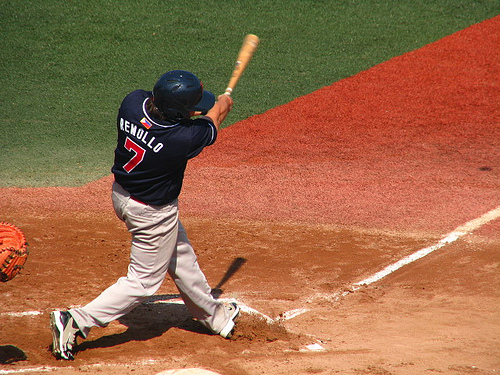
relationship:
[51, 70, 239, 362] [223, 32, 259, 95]
batter swinging bat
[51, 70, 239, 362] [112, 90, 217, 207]
batter has jersey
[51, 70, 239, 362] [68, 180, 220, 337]
batter wearing pants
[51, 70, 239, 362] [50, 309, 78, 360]
batter wearing shoe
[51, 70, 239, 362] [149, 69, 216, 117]
batter wearing helmet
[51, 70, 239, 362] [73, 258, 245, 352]
batter has shadow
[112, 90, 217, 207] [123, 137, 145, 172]
jersey has number 7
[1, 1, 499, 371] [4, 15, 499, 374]
field has sand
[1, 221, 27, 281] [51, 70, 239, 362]
glove behind batter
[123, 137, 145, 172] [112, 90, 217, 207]
number 7 on back of jersey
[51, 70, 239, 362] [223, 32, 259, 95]
batter using bat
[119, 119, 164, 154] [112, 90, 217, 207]
name on back of jersey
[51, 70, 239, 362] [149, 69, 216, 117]
batter has helmet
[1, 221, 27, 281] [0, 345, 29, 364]
glove has shadow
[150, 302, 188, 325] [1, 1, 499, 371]
home plate on top of field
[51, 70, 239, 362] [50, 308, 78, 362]
batter has right foot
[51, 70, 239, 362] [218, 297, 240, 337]
batter has left foot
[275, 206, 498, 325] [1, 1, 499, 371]
line on top of field